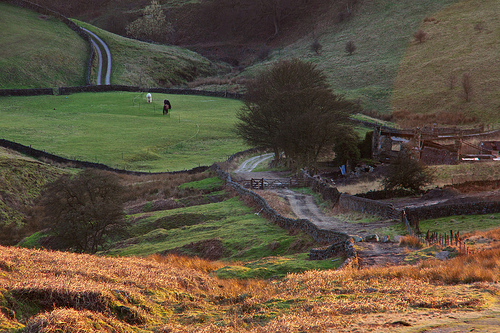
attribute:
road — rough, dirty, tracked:
[50, 10, 112, 87]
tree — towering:
[233, 58, 329, 169]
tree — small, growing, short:
[343, 40, 357, 56]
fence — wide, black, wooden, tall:
[236, 178, 314, 188]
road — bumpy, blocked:
[237, 151, 407, 266]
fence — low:
[215, 165, 353, 261]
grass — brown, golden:
[1, 244, 497, 330]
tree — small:
[333, 143, 364, 175]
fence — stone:
[0, 83, 243, 103]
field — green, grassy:
[3, 94, 275, 174]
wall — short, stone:
[296, 164, 413, 233]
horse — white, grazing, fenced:
[146, 93, 154, 103]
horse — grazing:
[163, 103, 170, 114]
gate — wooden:
[251, 176, 264, 192]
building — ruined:
[371, 126, 465, 168]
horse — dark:
[165, 97, 172, 107]